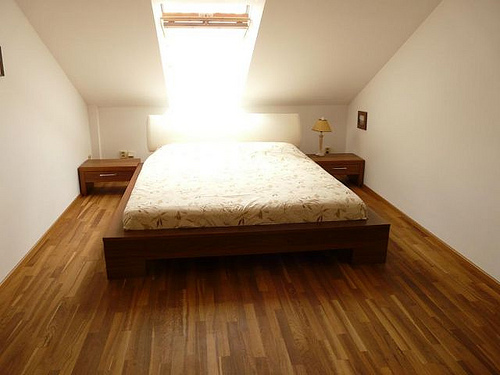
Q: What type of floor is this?
A: A wooden floor.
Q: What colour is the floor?
A: Brown.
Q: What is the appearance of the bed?
A: Neatly made.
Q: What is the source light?
A: The skylight.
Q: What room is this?
A: A bedroom.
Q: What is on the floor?
A: A bed.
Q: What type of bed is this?
A: A wooden bed.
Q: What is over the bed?
A: A skylight.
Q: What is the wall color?
A: White.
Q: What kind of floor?
A: Wooden.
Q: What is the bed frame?
A: Wooden.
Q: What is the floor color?
A: Brown.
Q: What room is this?
A: Bedroom.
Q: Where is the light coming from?
A: Ceiling.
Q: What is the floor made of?
A: Wood.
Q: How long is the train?
A: No train.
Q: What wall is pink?
A: No pink wall.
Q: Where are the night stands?
A: Beside bed.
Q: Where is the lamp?
A: Night stand.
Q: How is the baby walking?
A: No baby.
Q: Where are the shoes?
A: No shoes.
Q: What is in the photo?
A: Bed.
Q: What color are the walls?
A: Ivory.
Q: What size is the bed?
A: King.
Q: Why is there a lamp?
A: Light.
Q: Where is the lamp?
A: Table.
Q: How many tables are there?
A: Two.